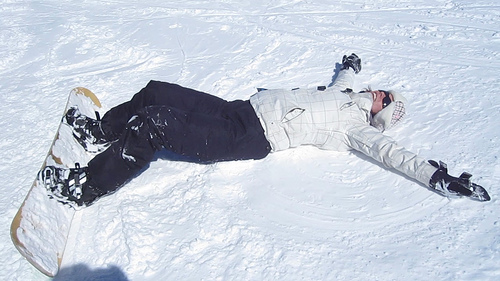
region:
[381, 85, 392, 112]
the snowboarder wears dark sunglasses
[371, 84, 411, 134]
a white knit cap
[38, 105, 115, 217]
a black pair of boots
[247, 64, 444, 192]
the snowboarder is wearing a white parka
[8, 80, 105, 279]
the snowboard is tan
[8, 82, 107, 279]
the snowboard is covered with snow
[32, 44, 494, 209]
the snowboarder is lying in the snow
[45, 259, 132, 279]
the photographer's shadow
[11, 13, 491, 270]
a snowboarder lying on the snow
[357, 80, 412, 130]
the head of a woman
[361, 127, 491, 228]
the arm of a woman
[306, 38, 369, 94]
the arm of a woman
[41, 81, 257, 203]
the legs of a woman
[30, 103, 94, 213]
the feet of a woman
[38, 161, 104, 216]
a snowboarder's boot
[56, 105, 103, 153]
a snowboarder's boot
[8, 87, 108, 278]
a wooden snowboard covered in snow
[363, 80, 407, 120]
a woman smiling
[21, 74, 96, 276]
The snowboard is brown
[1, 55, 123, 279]
The snowboard has snow on it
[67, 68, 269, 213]
The pants are black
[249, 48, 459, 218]
The jacket is white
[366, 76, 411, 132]
The hat is white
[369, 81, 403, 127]
The lady wears sunglasses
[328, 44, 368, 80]
The snowboarder wears gloves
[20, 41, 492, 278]
The snowboarder is on the snowboard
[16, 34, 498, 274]
The snowboarder is laying on the ground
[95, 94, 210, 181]
There is snow on the pants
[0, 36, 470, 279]
person laying in the snow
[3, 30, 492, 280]
woman laying in the snow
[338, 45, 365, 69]
black gloves on hand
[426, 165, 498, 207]
black snow gloves on hand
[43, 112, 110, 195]
black snow shoes on feet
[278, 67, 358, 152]
large white snow jacket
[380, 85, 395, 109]
sunglasses on face of p[erson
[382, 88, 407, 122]
white beanie of head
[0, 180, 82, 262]
white snow on top of board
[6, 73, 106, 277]
brown snow board on ground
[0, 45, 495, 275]
A person in black pants laying in the snow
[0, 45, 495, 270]
A person in a jacket laying in the snow making snow angels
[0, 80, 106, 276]
a brown snowboard covered in snow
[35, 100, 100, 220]
a pair of black boots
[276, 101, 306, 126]
a pocket in a jacket spread open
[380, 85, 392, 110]
a pair of black sunglasses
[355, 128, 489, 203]
a person's outstretched arm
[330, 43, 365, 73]
a black gloved hand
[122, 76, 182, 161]
a pair of bent knees in black pants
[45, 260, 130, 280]
a black shadow on the snow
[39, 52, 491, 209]
a snowboarder lying in the snow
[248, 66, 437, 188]
the white coat on the snowboarder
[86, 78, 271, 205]
the black pants on the snowboarder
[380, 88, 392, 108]
sunglasses on the snowboarder's face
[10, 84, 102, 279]
the snowboard the person is using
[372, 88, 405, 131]
the hat on the snowboarder's head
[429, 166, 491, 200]
the glove on the snowboarder's left hand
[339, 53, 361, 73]
the glove on the snowboarder's right hand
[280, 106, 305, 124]
the pocket in the coat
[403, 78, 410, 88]
white snow clump by the boarder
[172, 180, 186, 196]
white snow clump by the boarder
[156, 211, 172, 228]
white snow clump by the boarder